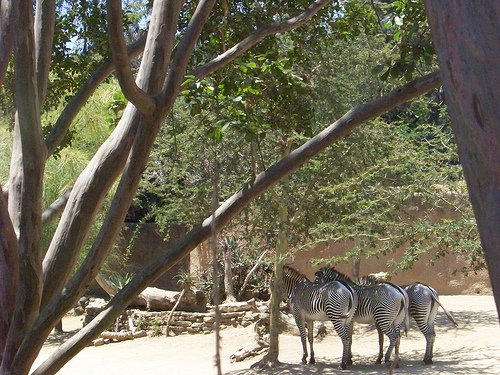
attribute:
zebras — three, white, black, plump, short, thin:
[285, 257, 451, 346]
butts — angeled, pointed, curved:
[327, 283, 361, 326]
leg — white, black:
[330, 321, 364, 347]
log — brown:
[144, 285, 219, 314]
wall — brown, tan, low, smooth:
[117, 307, 252, 349]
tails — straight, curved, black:
[438, 306, 468, 337]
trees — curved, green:
[212, 60, 357, 282]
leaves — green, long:
[260, 76, 277, 93]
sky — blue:
[67, 5, 151, 56]